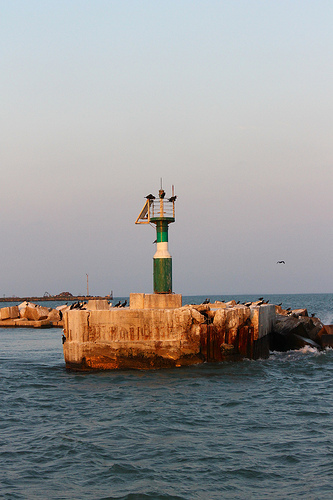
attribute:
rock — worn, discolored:
[74, 313, 212, 372]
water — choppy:
[11, 378, 323, 494]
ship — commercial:
[3, 292, 116, 301]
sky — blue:
[17, 15, 322, 178]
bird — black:
[55, 314, 64, 321]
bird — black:
[14, 303, 17, 309]